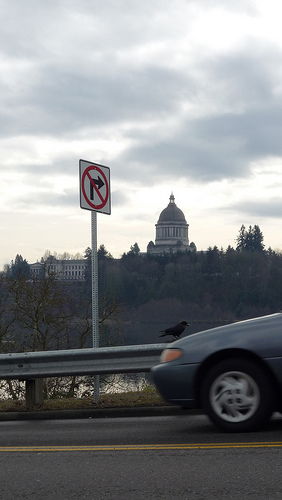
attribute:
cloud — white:
[4, 6, 274, 187]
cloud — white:
[220, 181, 281, 226]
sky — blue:
[6, 4, 281, 260]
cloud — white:
[17, 144, 74, 212]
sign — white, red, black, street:
[76, 158, 115, 218]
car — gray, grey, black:
[151, 303, 281, 436]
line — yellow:
[6, 443, 281, 448]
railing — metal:
[4, 344, 161, 370]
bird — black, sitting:
[158, 319, 190, 338]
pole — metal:
[87, 206, 100, 343]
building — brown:
[148, 190, 201, 252]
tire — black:
[194, 356, 278, 438]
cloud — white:
[8, 6, 194, 53]